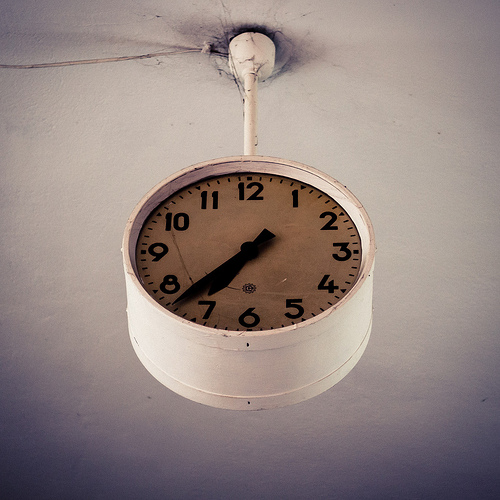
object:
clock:
[120, 155, 377, 412]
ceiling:
[2, 0, 499, 500]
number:
[236, 180, 265, 202]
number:
[290, 188, 302, 209]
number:
[319, 210, 340, 231]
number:
[317, 273, 340, 296]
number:
[282, 297, 307, 320]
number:
[197, 299, 218, 321]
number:
[147, 240, 170, 263]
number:
[163, 210, 192, 231]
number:
[198, 188, 220, 211]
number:
[158, 274, 181, 295]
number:
[237, 306, 261, 328]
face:
[136, 172, 363, 331]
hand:
[172, 228, 277, 303]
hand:
[208, 240, 252, 295]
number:
[332, 242, 353, 263]